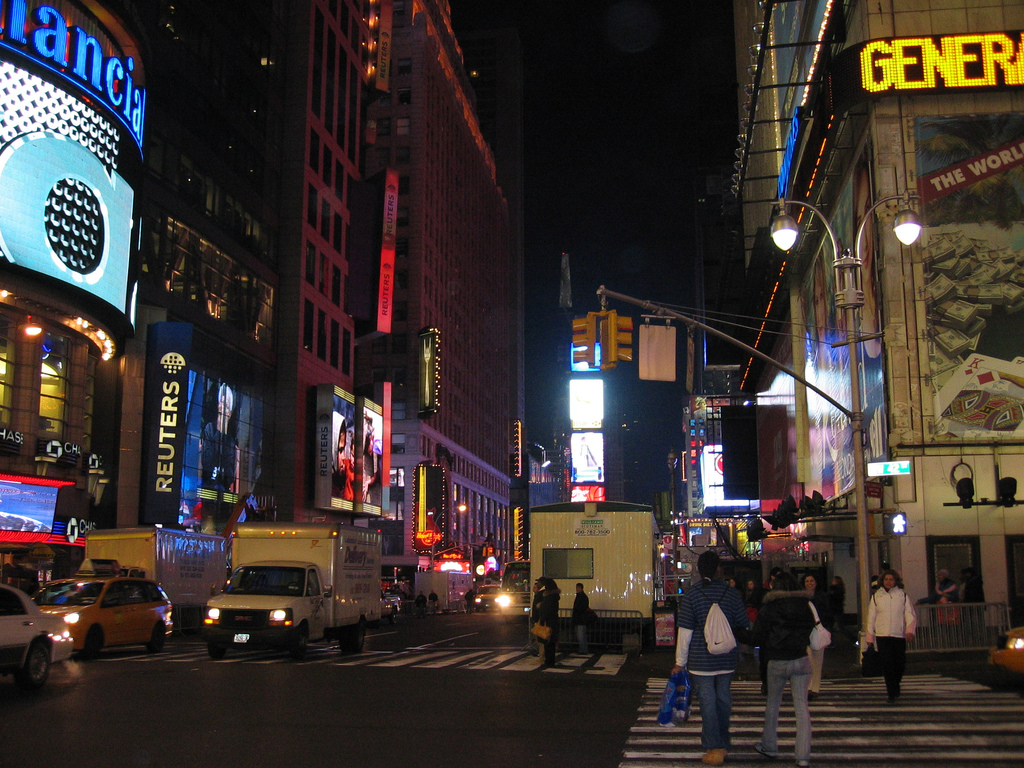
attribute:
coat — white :
[860, 587, 919, 639]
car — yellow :
[26, 569, 174, 658]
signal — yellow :
[566, 304, 640, 371]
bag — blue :
[656, 669, 698, 722]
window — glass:
[302, 181, 318, 216]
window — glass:
[289, 203, 326, 212]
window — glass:
[316, 200, 334, 229]